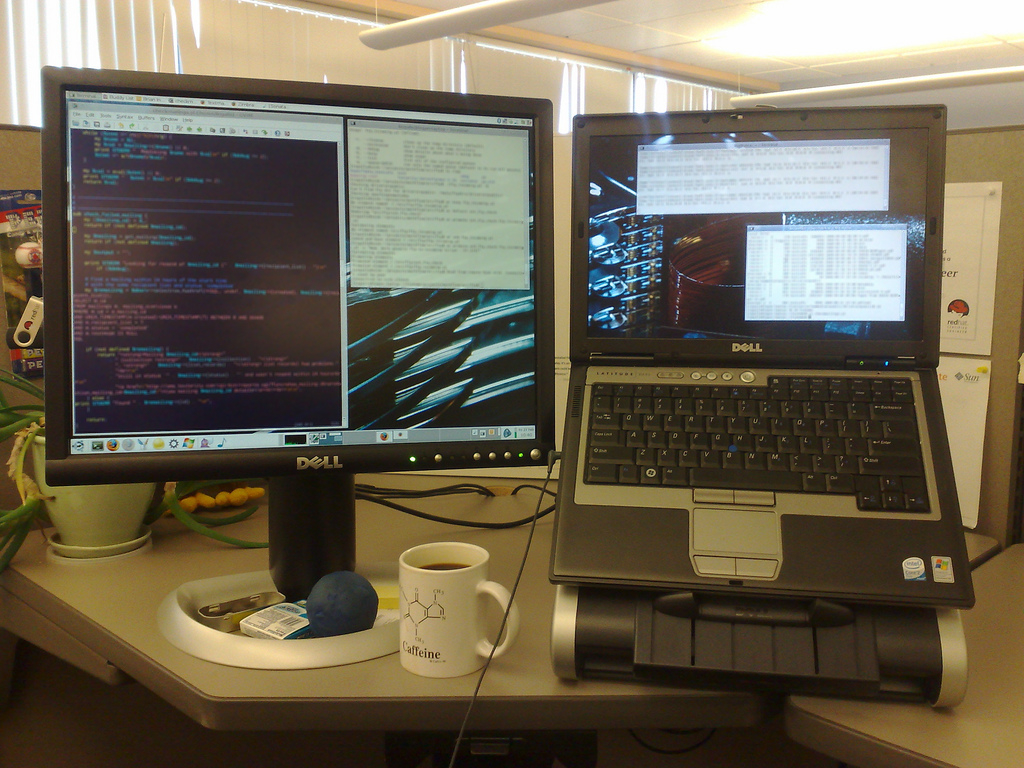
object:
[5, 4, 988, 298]
background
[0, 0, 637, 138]
curtain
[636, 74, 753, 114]
curtain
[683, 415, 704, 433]
key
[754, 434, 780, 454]
key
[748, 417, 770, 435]
key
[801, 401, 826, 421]
key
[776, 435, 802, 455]
key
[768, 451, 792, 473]
key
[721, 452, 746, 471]
key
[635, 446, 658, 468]
key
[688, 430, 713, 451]
key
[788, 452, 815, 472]
key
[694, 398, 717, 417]
key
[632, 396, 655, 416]
key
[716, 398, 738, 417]
key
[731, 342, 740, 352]
letters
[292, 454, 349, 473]
logo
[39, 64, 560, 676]
monitor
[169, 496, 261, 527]
leaf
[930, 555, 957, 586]
sticker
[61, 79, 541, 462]
screen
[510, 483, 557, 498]
wires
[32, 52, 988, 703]
computer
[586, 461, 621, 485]
keys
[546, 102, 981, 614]
computer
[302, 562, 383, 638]
ball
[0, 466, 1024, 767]
desk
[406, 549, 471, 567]
coffee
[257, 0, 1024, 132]
ceiling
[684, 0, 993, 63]
light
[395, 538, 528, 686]
coffee cup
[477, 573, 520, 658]
handle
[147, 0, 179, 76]
blinds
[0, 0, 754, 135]
windows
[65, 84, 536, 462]
image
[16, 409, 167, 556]
planter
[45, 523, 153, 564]
base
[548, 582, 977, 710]
stand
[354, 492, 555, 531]
wires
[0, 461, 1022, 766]
tabletop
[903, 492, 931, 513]
buttons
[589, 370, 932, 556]
computer keyboard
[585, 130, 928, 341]
image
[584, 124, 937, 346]
screen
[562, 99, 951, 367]
lid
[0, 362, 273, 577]
plant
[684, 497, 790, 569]
track pad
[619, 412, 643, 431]
key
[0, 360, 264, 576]
flower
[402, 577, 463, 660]
design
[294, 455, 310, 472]
letters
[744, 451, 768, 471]
key